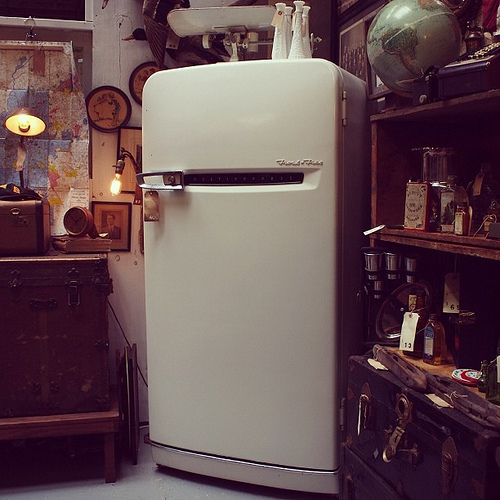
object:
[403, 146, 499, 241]
items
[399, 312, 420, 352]
tag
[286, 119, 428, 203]
person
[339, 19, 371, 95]
photo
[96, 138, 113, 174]
wall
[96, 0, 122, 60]
wall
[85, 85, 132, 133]
frame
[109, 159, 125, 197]
lamp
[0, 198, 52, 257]
chest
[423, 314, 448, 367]
antique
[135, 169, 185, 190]
handle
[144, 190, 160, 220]
tag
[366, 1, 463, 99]
globe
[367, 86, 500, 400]
shelf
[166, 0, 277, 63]
scale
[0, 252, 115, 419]
trunks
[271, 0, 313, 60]
four vases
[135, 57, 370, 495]
fridge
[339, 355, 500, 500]
chest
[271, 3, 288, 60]
vase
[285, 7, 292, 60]
vase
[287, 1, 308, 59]
vase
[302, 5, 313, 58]
vase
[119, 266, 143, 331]
wall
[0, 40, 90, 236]
map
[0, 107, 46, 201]
lamp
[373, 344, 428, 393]
antique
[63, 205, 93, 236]
alarm clock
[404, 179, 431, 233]
antique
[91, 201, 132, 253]
frame